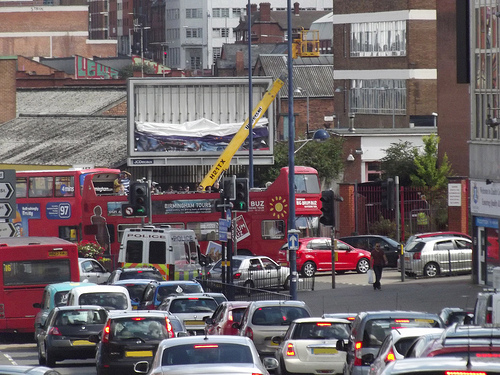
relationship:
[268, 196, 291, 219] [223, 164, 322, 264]
sun on bus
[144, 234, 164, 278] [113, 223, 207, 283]
door on van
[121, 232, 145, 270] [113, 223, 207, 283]
door on van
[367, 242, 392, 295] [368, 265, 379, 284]
person carrying a bag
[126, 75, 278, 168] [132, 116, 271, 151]
billboard being changed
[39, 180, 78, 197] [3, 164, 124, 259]
peopel are sitting on bus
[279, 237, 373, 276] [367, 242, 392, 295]
car behind person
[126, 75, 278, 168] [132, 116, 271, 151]
billboard has changed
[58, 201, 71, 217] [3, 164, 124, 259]
number on bus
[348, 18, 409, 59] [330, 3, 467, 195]
windows are on building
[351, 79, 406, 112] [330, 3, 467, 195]
windows are on building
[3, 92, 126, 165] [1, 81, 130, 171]
roof on a building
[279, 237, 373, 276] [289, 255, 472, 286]
car on street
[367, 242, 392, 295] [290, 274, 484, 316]
person on sidewalk